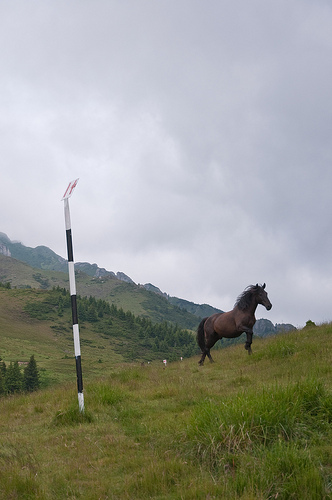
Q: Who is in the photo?
A: Nobody.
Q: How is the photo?
A: Clear.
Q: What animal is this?
A: A horse.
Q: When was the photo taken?
A: Daytime.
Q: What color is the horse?
A: Brown.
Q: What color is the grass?
A: Green.